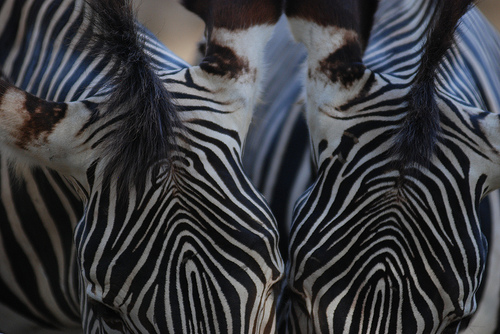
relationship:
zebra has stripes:
[36, 48, 274, 332] [158, 234, 208, 277]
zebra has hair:
[36, 48, 274, 332] [111, 82, 190, 159]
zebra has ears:
[36, 48, 274, 332] [191, 8, 264, 107]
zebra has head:
[36, 48, 274, 332] [79, 194, 276, 271]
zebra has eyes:
[36, 48, 274, 332] [68, 274, 145, 331]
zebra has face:
[36, 48, 274, 332] [256, 246, 300, 279]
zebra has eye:
[36, 48, 274, 332] [249, 271, 289, 303]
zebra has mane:
[36, 48, 274, 332] [396, 31, 457, 150]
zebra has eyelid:
[36, 48, 274, 332] [76, 286, 115, 301]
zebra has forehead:
[36, 48, 274, 332] [130, 184, 227, 256]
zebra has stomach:
[36, 48, 274, 332] [228, 99, 325, 175]